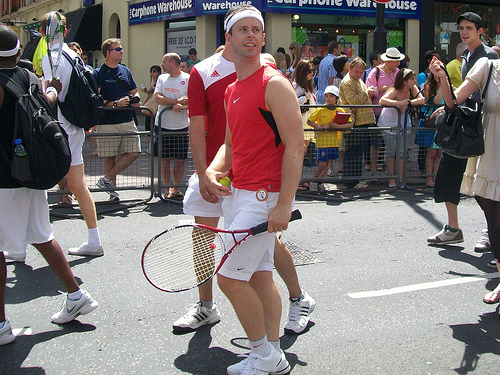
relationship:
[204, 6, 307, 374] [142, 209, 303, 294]
player holding tennis racket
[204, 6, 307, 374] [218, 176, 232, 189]
player holding tennis ball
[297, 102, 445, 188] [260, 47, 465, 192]
barrier holding back crowd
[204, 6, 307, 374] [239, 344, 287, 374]
player wearing shoe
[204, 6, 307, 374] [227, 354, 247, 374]
player wearing shoe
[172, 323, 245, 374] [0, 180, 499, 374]
shadow on street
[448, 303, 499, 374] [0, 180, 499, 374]
shadow on street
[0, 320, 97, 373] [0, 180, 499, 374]
shadow on street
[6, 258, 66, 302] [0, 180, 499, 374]
shadow on street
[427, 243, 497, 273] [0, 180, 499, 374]
shadow on street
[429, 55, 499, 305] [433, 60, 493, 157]
woman holding purse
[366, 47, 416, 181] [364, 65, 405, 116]
man in shirt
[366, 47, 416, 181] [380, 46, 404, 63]
man wearing hat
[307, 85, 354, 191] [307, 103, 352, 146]
boy wearing shirt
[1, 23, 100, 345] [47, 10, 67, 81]
player holding tennis racket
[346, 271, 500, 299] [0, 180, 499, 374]
stripe on street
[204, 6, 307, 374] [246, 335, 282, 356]
player wearing socks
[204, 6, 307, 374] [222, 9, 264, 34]
player wearing sweatband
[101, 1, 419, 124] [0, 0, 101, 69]
building next to building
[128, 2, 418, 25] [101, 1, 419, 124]
sign on building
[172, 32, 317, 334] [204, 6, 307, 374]
man behind player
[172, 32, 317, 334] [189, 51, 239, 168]
man wearing shirt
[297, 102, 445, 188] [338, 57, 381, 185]
barrier in front of person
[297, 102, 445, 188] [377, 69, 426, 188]
barrier in front of person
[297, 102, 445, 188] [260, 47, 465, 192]
barrier keeping back crowd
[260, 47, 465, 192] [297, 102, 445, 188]
crowd behind barrier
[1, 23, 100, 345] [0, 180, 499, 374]
player walking on street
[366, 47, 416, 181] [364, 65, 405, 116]
man wearing shirt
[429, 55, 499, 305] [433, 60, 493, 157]
woman carrying purse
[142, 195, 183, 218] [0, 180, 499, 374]
shadow on street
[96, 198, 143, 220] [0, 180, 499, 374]
shadow on street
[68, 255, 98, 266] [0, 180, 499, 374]
shadow on street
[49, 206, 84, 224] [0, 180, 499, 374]
shadow on street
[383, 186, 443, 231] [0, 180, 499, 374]
shadow on street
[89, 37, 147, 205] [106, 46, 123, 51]
man wearing sunglasses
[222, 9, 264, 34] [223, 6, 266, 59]
sweatband on head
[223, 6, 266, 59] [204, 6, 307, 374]
head on player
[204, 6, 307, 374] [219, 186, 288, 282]
player wearing shorts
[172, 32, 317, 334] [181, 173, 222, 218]
man wearing shorts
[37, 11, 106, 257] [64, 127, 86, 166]
man wearing shorts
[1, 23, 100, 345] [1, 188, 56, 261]
player wearing shorts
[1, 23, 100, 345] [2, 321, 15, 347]
player wearing shoe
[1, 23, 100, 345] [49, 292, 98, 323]
player wearing shoe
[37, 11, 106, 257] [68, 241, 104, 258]
man wearing shoe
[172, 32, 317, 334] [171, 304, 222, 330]
man wearing shoe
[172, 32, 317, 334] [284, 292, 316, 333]
man wearing shoe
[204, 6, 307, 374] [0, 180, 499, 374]
player walking on street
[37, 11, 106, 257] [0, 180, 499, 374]
man walking on street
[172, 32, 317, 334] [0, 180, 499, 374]
man walking on street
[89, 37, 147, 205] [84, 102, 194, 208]
man behind barrier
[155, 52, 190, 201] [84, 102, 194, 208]
man behind barrier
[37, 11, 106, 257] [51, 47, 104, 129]
man carrying backpack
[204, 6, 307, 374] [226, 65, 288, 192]
player wearing shirt